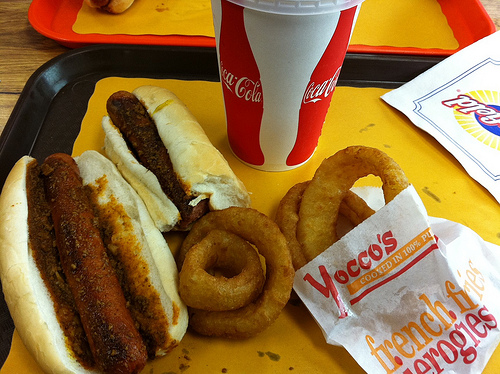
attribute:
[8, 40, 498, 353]
tray — black, brown, red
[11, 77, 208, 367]
hotdogs — here, cooked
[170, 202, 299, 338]
onion rings — here, breaded, fried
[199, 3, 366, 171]
cup — red, white, paper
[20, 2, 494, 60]
tray — orange, plastic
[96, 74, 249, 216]
chili dog — half, eaten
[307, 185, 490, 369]
bag — red orange white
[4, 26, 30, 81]
table — wooden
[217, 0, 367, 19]
lid — plastic